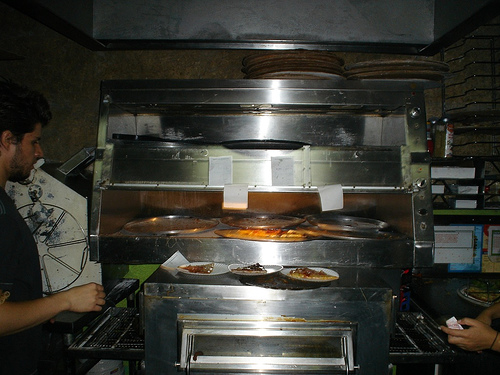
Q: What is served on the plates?
A: Pizza.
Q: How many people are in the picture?
A: Two.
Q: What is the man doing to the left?
A: Looking at the pizzas.